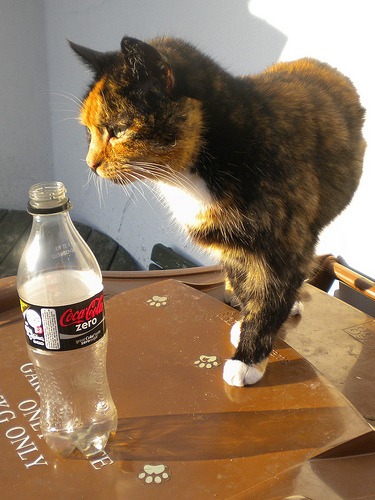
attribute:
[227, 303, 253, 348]
paw — cat, white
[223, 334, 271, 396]
paw — cat, white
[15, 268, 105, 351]
label — soda, brand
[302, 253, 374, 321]
handle —  WOOD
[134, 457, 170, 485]
sticker — paw print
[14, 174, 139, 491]
bottle — clear 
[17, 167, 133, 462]
bottle — coke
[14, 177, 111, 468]
bottle — zero, coke, empty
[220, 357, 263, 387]
cat paw — white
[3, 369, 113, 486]
words — printed, white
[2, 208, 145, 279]
table —  wood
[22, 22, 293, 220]
cat — orange, black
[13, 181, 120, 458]
bottle — empty, coke, zero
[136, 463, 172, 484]
pawprints — white, three, little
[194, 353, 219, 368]
pawprints — white, three, little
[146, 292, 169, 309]
pawprints — white, three, little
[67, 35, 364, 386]
cat — leg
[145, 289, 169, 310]
paw print — cream , brown 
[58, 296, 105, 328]
identification —  for Coca Cola Zero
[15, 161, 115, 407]
bottle — empty, coke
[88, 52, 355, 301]
cat — w/ FACE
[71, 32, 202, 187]
face — cat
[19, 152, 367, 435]
chair —  wooden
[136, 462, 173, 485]
paw print — small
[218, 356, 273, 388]
paw —  Cat's,  sticker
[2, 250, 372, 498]
furniture piece — wooden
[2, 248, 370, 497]
top —  wooden